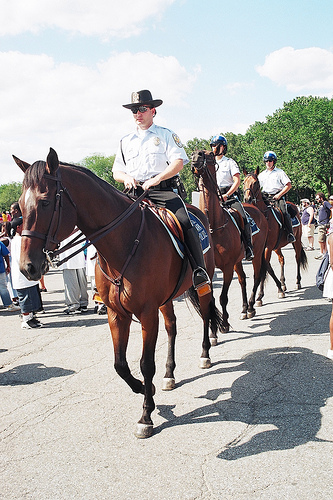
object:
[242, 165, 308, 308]
horse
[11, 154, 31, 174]
ear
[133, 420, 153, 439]
hoof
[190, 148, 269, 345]
horse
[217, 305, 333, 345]
shadow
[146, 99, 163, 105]
brim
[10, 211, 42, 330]
child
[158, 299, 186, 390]
back legs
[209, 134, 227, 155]
helmet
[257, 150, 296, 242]
officer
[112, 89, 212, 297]
cops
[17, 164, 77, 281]
face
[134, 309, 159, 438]
left leg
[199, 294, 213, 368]
leg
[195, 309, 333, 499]
cracked line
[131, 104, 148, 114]
sunglasses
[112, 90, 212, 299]
officer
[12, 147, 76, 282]
head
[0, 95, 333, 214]
tree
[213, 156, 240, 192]
shirt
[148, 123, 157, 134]
lapel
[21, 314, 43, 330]
sneakers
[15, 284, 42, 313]
shorts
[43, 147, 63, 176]
ear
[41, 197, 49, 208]
eye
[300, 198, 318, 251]
man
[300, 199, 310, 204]
cap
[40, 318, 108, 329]
shadow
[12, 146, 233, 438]
horse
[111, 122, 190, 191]
shirt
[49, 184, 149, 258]
strap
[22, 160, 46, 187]
hair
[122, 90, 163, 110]
hat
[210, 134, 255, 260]
officer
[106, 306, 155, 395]
leg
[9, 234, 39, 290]
t-shirt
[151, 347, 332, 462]
horse's shadow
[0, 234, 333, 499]
ground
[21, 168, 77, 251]
bridle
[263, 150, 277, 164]
helmet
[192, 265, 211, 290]
stirrups